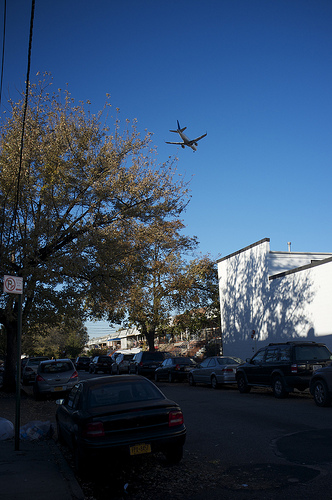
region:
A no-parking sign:
[4, 267, 36, 297]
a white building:
[196, 221, 330, 349]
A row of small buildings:
[72, 305, 219, 350]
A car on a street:
[29, 366, 195, 452]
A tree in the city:
[96, 215, 211, 353]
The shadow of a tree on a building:
[231, 270, 265, 328]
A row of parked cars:
[64, 336, 331, 391]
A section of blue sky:
[209, 213, 239, 236]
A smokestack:
[284, 239, 294, 253]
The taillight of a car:
[152, 404, 196, 433]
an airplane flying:
[163, 119, 210, 161]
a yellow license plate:
[128, 441, 156, 456]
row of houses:
[85, 317, 215, 351]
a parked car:
[49, 373, 199, 470]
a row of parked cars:
[133, 341, 321, 398]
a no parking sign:
[0, 269, 27, 296]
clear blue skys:
[233, 155, 329, 225]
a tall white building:
[213, 238, 327, 351]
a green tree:
[95, 262, 205, 358]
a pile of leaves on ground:
[149, 464, 284, 496]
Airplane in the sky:
[163, 117, 209, 154]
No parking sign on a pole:
[2, 274, 26, 295]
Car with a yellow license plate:
[54, 369, 187, 460]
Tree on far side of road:
[85, 239, 218, 355]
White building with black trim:
[215, 236, 330, 355]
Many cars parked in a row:
[74, 340, 331, 390]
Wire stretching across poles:
[3, 0, 39, 262]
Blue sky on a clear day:
[1, 1, 331, 308]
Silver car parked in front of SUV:
[188, 354, 242, 386]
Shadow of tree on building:
[217, 238, 312, 342]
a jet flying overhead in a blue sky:
[157, 114, 209, 154]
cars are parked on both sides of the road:
[23, 340, 328, 475]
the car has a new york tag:
[125, 440, 151, 454]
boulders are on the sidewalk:
[0, 415, 56, 443]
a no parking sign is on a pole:
[5, 270, 29, 444]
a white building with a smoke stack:
[212, 239, 331, 380]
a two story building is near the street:
[55, 307, 222, 369]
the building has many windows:
[67, 313, 222, 356]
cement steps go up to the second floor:
[173, 338, 206, 365]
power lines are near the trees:
[1, 1, 23, 264]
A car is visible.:
[62, 370, 149, 479]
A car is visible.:
[87, 393, 134, 466]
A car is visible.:
[87, 422, 135, 496]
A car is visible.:
[91, 392, 153, 491]